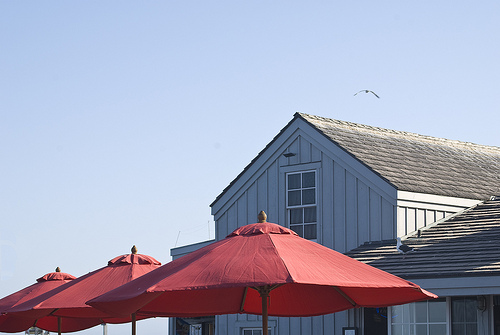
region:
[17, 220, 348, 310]
red umbrellas outside building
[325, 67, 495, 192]
grey roof on building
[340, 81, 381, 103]
bird is above building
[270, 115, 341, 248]
white frame on windows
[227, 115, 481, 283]
building has pointed roof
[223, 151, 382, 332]
building has grey exterior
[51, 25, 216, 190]
sky is blue and clear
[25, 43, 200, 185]
no clouds in sky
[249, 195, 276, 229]
brown tip on umbrella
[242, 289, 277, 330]
wooden pole under umbrella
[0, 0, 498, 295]
Clear sky at day time.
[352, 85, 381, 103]
Bird flying in the sky.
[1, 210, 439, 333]
Three red umbrellas with brown poles.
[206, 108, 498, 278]
Dark grey roof top shingles.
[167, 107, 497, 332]
White and grey building.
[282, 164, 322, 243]
Window with eight panes of glass.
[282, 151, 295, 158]
Small light on side of building.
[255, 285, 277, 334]
Brown pole of an umbrella.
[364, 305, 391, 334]
Screen window on the side of building.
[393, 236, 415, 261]
Seagull standing on the roof.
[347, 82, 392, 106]
probably a seagull flying above beachfront shopping area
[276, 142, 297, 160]
possibly a parked seabird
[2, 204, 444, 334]
three deep red umbrellas, likely above cafe tables beside the sand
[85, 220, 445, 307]
slightly squared panels in a triangular or conical shaped patio umbrella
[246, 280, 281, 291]
parts of several 'short ribs'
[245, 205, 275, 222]
brown wooden finial top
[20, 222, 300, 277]
the top red bits are called 'vents'; you have three of them here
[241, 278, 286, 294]
all of this together is the 'rib assembly'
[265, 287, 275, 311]
pull cord is called 'pulley'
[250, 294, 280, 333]
pole, of course, this one appears wooden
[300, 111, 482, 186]
the roof of the house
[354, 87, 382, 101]
the bird in the air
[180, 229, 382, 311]
a red umbrella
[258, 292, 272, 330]
the pole holding an umbrella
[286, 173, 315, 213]
the window of a house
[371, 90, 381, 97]
the wing of a bird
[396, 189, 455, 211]
the fresher board of a house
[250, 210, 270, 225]
the tip of an umbrella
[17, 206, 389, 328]
three standing umbrella's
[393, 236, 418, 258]
a bird on the roof